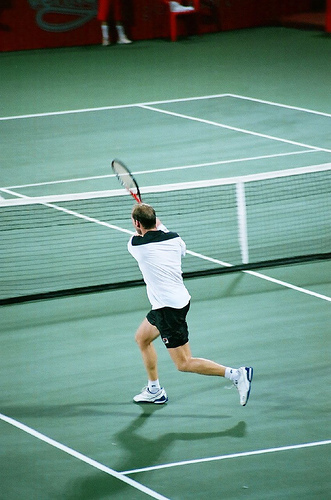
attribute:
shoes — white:
[111, 349, 284, 426]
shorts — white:
[141, 295, 216, 353]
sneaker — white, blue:
[236, 366, 252, 405]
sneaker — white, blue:
[133, 385, 167, 404]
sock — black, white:
[144, 375, 166, 396]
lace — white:
[121, 374, 157, 403]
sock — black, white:
[225, 366, 236, 382]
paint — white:
[1, 402, 326, 497]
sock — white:
[223, 365, 241, 381]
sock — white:
[144, 378, 161, 393]